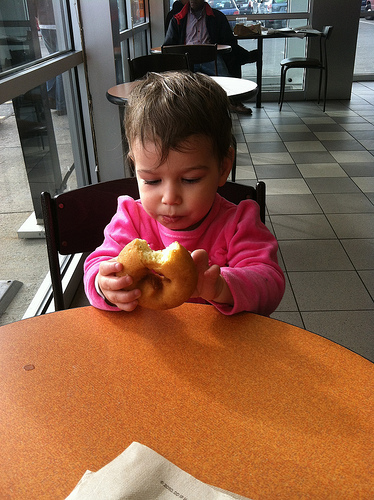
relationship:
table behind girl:
[35, 337, 354, 432] [77, 79, 293, 299]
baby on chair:
[83, 70, 287, 315] [34, 170, 280, 305]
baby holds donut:
[83, 70, 287, 315] [105, 232, 198, 314]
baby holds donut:
[83, 70, 287, 315] [113, 240, 195, 312]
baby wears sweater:
[83, 70, 287, 315] [82, 189, 284, 317]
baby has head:
[83, 70, 287, 315] [113, 61, 252, 248]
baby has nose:
[83, 70, 287, 315] [161, 191, 183, 207]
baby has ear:
[83, 70, 287, 315] [212, 135, 240, 187]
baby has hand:
[83, 70, 287, 315] [98, 258, 143, 314]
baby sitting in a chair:
[98, 93, 293, 288] [26, 170, 249, 268]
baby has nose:
[83, 70, 287, 315] [158, 174, 181, 212]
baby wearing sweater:
[83, 70, 287, 315] [82, 189, 284, 317]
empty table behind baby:
[106, 71, 260, 103] [83, 70, 287, 315]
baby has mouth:
[83, 70, 287, 315] [156, 210, 192, 224]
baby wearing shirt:
[83, 70, 287, 315] [79, 184, 289, 323]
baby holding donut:
[83, 70, 287, 315] [111, 234, 201, 313]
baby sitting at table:
[83, 70, 287, 315] [0, 301, 371, 498]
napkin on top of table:
[57, 441, 249, 496] [0, 301, 371, 498]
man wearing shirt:
[160, 8, 250, 113] [168, 8, 224, 47]